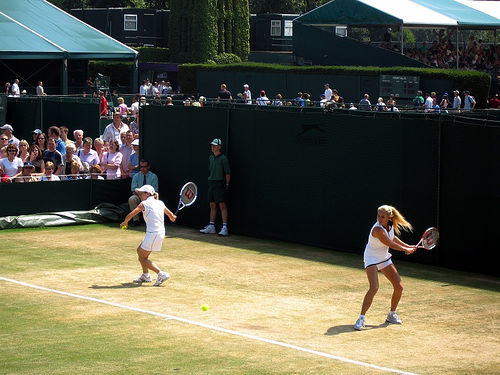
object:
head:
[138, 184, 155, 201]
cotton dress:
[363, 222, 393, 269]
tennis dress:
[363, 220, 392, 270]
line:
[0, 275, 417, 375]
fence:
[136, 103, 500, 275]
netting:
[182, 184, 195, 204]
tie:
[143, 174, 146, 185]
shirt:
[141, 195, 165, 232]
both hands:
[405, 244, 416, 255]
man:
[128, 157, 158, 227]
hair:
[378, 204, 415, 236]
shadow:
[88, 278, 166, 288]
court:
[0, 220, 490, 374]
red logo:
[185, 188, 194, 200]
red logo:
[426, 231, 434, 246]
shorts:
[140, 233, 165, 251]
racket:
[405, 227, 440, 255]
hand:
[405, 248, 416, 254]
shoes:
[354, 319, 364, 331]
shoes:
[386, 312, 402, 323]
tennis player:
[353, 204, 418, 331]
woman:
[119, 184, 177, 286]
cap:
[135, 184, 156, 195]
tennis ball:
[201, 306, 208, 312]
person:
[462, 90, 477, 112]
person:
[454, 90, 462, 112]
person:
[439, 93, 448, 113]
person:
[423, 93, 434, 112]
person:
[358, 94, 373, 111]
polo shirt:
[207, 152, 231, 181]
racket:
[174, 181, 198, 215]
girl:
[353, 205, 417, 331]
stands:
[0, 94, 499, 127]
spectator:
[62, 143, 83, 179]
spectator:
[102, 138, 123, 179]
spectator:
[0, 143, 24, 179]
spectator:
[43, 137, 64, 174]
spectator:
[101, 112, 130, 146]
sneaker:
[218, 228, 229, 237]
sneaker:
[200, 226, 216, 234]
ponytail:
[390, 205, 414, 235]